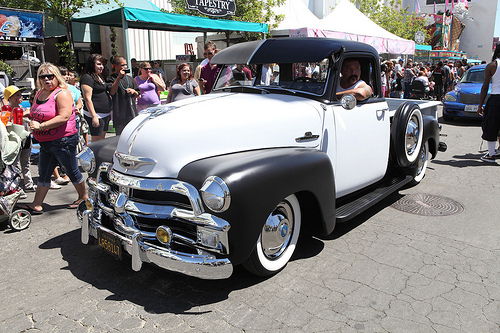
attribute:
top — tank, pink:
[28, 90, 78, 140]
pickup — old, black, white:
[87, 38, 442, 283]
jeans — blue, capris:
[37, 140, 87, 185]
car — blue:
[446, 60, 499, 119]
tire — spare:
[394, 106, 424, 164]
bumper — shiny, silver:
[76, 166, 230, 280]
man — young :
[108, 55, 135, 137]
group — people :
[82, 39, 246, 134]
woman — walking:
[19, 60, 90, 217]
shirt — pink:
[25, 80, 81, 137]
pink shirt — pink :
[27, 85, 79, 144]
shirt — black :
[79, 70, 117, 112]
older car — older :
[77, 33, 448, 281]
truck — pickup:
[43, 15, 460, 307]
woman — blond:
[30, 63, 72, 160]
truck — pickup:
[79, 31, 448, 284]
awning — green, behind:
[75, 4, 254, 56]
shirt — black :
[104, 72, 137, 123]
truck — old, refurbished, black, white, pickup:
[82, 62, 434, 282]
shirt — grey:
[165, 77, 201, 101]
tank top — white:
[488, 58, 499, 93]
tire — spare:
[382, 92, 440, 177]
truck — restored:
[108, 34, 448, 277]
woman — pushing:
[30, 35, 107, 232]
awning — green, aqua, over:
[68, 0, 268, 37]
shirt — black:
[106, 66, 139, 118]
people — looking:
[87, 55, 194, 95]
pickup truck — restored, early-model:
[76, 35, 448, 284]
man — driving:
[331, 55, 374, 98]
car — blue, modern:
[438, 59, 498, 124]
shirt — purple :
[130, 69, 166, 115]